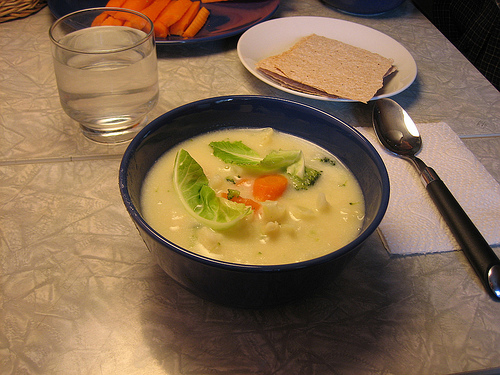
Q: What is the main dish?
A: Soup.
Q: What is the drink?
A: Water.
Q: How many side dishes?
A: Two.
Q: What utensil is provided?
A: Spoon.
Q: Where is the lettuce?
A: In the soup bowl.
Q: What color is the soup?
A: Yellow.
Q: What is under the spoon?
A: A napkin.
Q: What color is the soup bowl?
A: Blue.